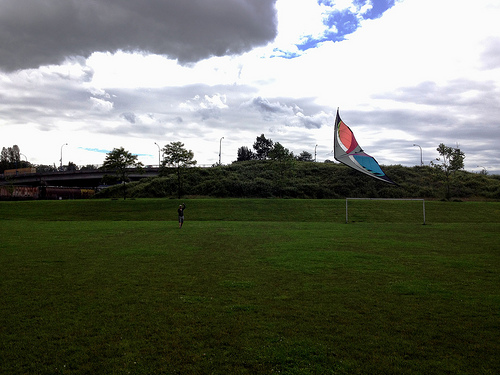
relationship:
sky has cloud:
[0, 1, 500, 174] [1, 0, 278, 75]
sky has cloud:
[0, 1, 500, 174] [377, 74, 500, 106]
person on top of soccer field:
[176, 202, 187, 225] [0, 219, 498, 374]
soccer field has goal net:
[0, 219, 498, 374] [344, 196, 425, 224]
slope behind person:
[0, 197, 500, 222] [176, 202, 187, 225]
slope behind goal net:
[0, 197, 500, 222] [344, 196, 425, 224]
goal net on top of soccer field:
[344, 196, 425, 224] [0, 219, 498, 374]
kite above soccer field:
[333, 107, 403, 187] [0, 219, 498, 374]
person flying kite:
[176, 202, 187, 225] [333, 107, 403, 187]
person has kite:
[176, 202, 187, 225] [333, 107, 403, 187]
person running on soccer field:
[176, 202, 187, 225] [0, 219, 498, 374]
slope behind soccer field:
[0, 197, 500, 222] [0, 219, 498, 374]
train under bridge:
[0, 185, 99, 199] [1, 173, 163, 182]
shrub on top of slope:
[281, 185, 307, 197] [0, 197, 500, 222]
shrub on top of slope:
[208, 183, 230, 198] [0, 197, 500, 222]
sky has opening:
[0, 1, 500, 174] [278, 1, 395, 62]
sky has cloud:
[0, 1, 500, 174] [177, 95, 232, 121]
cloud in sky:
[93, 98, 114, 119] [0, 1, 500, 174]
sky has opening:
[0, 1, 500, 174] [90, 148, 149, 159]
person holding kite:
[176, 202, 187, 225] [333, 107, 403, 187]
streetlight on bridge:
[60, 142, 67, 169] [1, 173, 163, 182]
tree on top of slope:
[431, 140, 463, 199] [0, 197, 500, 222]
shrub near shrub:
[377, 188, 410, 197] [415, 185, 439, 197]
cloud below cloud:
[335, 107, 500, 140] [478, 35, 499, 72]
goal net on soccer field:
[344, 196, 425, 224] [0, 219, 498, 374]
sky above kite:
[0, 1, 500, 174] [333, 107, 403, 187]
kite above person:
[333, 107, 403, 187] [176, 202, 187, 225]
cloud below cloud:
[293, 114, 322, 128] [256, 97, 295, 117]